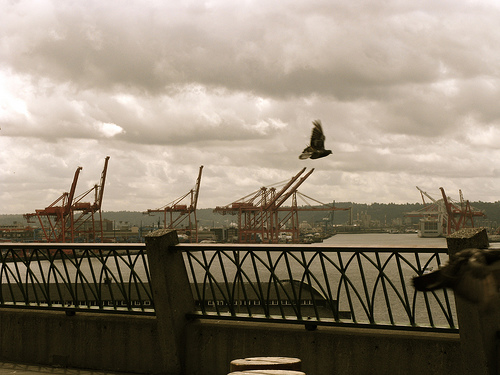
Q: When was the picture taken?
A: Daytime.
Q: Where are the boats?
A: In the far background.